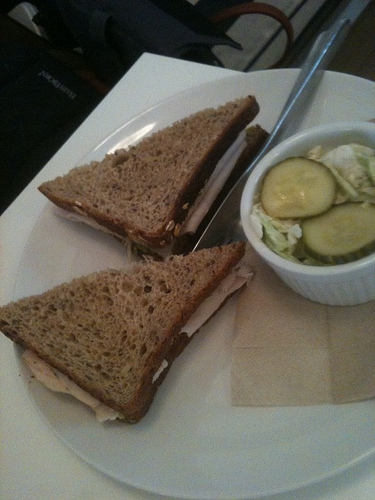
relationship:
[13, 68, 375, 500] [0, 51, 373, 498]
plate on top of mat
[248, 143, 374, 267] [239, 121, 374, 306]
coleslaw inside ramekin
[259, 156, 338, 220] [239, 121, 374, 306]
pickle inside ramekin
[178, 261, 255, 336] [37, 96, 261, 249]
meat inside bread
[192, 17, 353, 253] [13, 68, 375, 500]
knife sitting on plate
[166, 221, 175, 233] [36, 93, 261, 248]
oat stuck to bread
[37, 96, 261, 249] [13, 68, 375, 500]
bread on top of plate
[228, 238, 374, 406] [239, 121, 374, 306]
napkin under ramekin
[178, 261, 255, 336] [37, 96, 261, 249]
meat hanging from bread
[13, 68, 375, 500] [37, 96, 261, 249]
plate with bread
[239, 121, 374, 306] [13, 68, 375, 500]
ramekin on top of plate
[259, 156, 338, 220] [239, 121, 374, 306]
pickle inside of ramekin